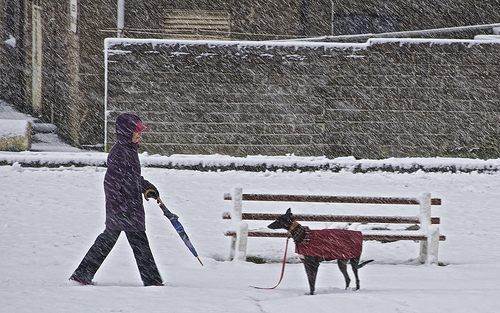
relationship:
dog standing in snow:
[264, 204, 372, 304] [4, 286, 499, 311]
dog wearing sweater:
[264, 204, 372, 304] [294, 225, 362, 261]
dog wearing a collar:
[264, 204, 372, 304] [287, 219, 298, 232]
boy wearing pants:
[68, 111, 164, 287] [69, 222, 164, 291]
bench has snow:
[216, 183, 443, 267] [233, 190, 248, 260]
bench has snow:
[216, 183, 443, 267] [420, 190, 439, 262]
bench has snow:
[216, 183, 443, 267] [249, 227, 424, 239]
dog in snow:
[266, 207, 374, 296] [382, 271, 487, 305]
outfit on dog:
[286, 221, 366, 265] [264, 204, 372, 304]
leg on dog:
[349, 260, 366, 292] [273, 212, 370, 296]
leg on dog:
[339, 256, 351, 288] [273, 212, 370, 296]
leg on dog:
[305, 256, 319, 293] [273, 212, 370, 296]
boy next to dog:
[68, 111, 164, 287] [264, 204, 372, 304]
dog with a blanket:
[266, 207, 374, 296] [303, 226, 364, 263]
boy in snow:
[65, 111, 164, 286] [2, 2, 498, 312]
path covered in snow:
[1, 250, 498, 310] [1, 160, 498, 311]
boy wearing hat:
[68, 111, 164, 287] [130, 120, 149, 133]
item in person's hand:
[137, 178, 209, 270] [144, 187, 163, 200]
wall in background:
[105, 39, 498, 158] [34, 3, 448, 150]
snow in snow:
[3, 167, 75, 307] [442, 167, 496, 311]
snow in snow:
[3, 167, 75, 307] [161, 145, 494, 198]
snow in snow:
[3, 167, 75, 307] [65, 285, 460, 311]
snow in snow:
[3, 167, 75, 307] [3, 5, 99, 124]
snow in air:
[3, 167, 75, 307] [16, 30, 85, 141]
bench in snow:
[221, 183, 446, 267] [220, 170, 474, 217]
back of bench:
[218, 188, 447, 239] [216, 183, 443, 267]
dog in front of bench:
[266, 207, 374, 296] [216, 183, 443, 267]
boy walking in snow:
[68, 111, 164, 287] [453, 230, 478, 270]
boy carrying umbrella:
[68, 111, 164, 287] [140, 187, 205, 267]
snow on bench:
[0, 147, 498, 309] [226, 185, 452, 242]